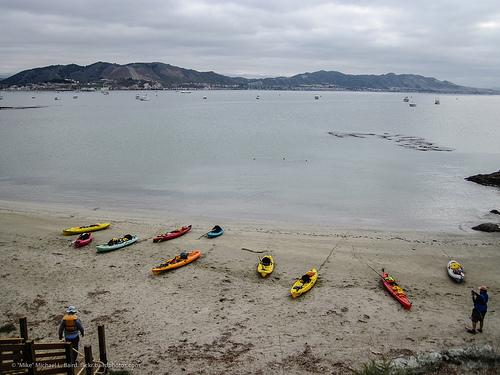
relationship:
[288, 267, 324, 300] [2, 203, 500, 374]
kayak on sand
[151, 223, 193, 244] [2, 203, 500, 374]
kayak on sand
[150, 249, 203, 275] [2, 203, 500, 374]
kayak on sand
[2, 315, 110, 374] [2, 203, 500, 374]
rail leading to beach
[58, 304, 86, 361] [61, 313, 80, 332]
man wearing vest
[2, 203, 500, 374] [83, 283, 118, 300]
sand covered by seaweed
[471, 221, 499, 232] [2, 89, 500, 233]
rock in water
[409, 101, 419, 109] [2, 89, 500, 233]
boat on water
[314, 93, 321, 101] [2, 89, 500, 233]
boat in water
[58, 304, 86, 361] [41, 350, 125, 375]
man near stairs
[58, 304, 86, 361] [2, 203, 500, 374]
man standing on sand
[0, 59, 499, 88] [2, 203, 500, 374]
hills distance from sand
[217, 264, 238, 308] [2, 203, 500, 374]
imprints on sand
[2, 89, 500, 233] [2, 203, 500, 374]
water near sand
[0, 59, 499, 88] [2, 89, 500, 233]
hills near water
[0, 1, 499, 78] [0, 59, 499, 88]
clouds over hills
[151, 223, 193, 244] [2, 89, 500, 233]
kayak near water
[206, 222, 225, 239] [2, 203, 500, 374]
kayak on sand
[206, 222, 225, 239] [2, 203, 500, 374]
kayak in sand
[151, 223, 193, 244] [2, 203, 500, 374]
kayak in sand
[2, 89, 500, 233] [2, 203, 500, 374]
water between sand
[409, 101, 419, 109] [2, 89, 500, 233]
boat in water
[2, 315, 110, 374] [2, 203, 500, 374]
rail on sand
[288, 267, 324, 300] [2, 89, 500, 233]
kayak near water